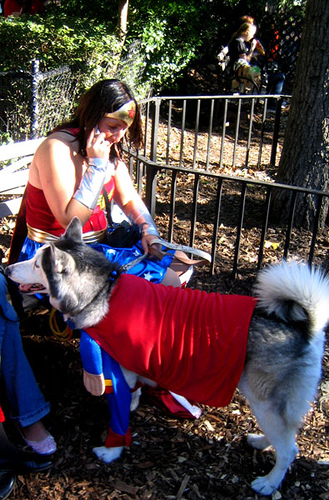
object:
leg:
[250, 399, 300, 498]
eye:
[34, 261, 40, 269]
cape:
[77, 272, 259, 447]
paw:
[246, 433, 264, 449]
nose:
[5, 264, 12, 277]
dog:
[3, 214, 329, 496]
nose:
[112, 130, 123, 143]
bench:
[7, 180, 81, 339]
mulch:
[161, 444, 235, 498]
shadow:
[155, 191, 295, 227]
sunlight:
[176, 125, 280, 170]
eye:
[107, 124, 116, 131]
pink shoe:
[17, 420, 58, 455]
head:
[4, 215, 84, 316]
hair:
[43, 78, 143, 168]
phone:
[84, 124, 104, 144]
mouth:
[8, 275, 46, 295]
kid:
[228, 14, 256, 65]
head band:
[104, 100, 136, 127]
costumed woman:
[14, 78, 193, 292]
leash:
[116, 238, 211, 273]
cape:
[1, 220, 14, 240]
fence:
[117, 94, 328, 276]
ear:
[63, 216, 83, 246]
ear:
[48, 241, 74, 272]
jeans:
[0, 273, 51, 428]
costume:
[16, 122, 179, 299]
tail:
[251, 257, 329, 338]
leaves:
[149, 25, 163, 39]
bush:
[0, 0, 306, 142]